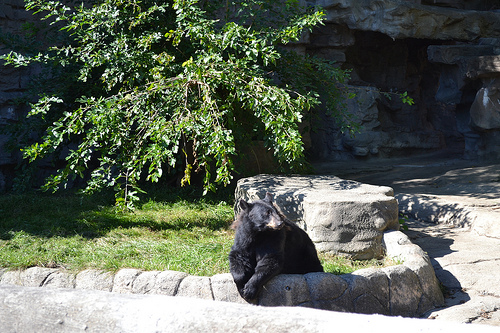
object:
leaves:
[25, 91, 65, 123]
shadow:
[142, 214, 231, 230]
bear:
[226, 192, 326, 306]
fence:
[0, 232, 447, 313]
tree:
[0, 2, 333, 218]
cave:
[304, 17, 499, 162]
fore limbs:
[244, 231, 289, 308]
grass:
[6, 215, 85, 266]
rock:
[311, 176, 398, 259]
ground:
[320, 238, 353, 247]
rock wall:
[422, 42, 497, 158]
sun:
[467, 238, 500, 320]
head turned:
[239, 190, 287, 233]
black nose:
[277, 219, 286, 228]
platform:
[233, 173, 397, 204]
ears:
[262, 190, 275, 203]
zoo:
[0, 0, 500, 333]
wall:
[0, 1, 495, 162]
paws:
[242, 282, 265, 305]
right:
[472, 5, 494, 326]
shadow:
[0, 205, 84, 232]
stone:
[289, 168, 404, 258]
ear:
[233, 196, 253, 214]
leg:
[228, 238, 253, 303]